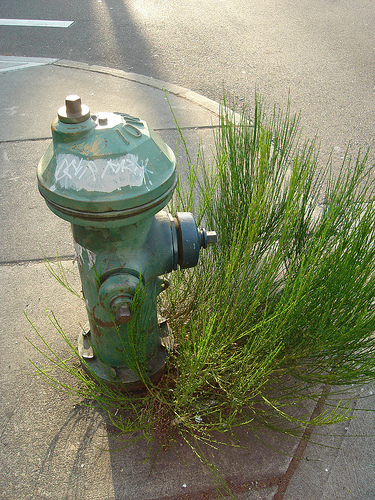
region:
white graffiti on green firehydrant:
[50, 154, 157, 199]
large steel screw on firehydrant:
[167, 206, 222, 279]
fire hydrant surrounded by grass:
[50, 294, 323, 452]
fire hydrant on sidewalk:
[12, 44, 198, 392]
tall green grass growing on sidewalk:
[191, 102, 353, 414]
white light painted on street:
[2, 11, 125, 42]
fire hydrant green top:
[35, 89, 181, 220]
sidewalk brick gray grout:
[247, 454, 309, 494]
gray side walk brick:
[4, 397, 59, 477]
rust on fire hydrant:
[87, 275, 137, 362]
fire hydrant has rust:
[0, 73, 215, 412]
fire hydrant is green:
[57, 95, 210, 436]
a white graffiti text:
[45, 143, 155, 208]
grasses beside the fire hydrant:
[154, 180, 302, 496]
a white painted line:
[29, 8, 137, 74]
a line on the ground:
[1, 10, 117, 60]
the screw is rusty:
[99, 296, 152, 346]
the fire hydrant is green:
[39, 114, 184, 390]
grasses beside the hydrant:
[96, 311, 311, 485]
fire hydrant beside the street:
[39, 39, 247, 396]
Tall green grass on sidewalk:
[147, 86, 368, 473]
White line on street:
[1, 6, 79, 37]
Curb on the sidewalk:
[37, 51, 347, 226]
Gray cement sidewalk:
[1, 50, 370, 496]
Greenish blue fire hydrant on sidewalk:
[26, 96, 215, 397]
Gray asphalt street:
[1, 0, 373, 210]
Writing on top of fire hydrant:
[105, 107, 151, 147]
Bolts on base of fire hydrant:
[68, 316, 184, 386]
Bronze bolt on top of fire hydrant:
[50, 92, 98, 128]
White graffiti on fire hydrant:
[44, 151, 149, 198]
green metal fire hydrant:
[42, 90, 205, 425]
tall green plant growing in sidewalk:
[171, 127, 374, 452]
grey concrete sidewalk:
[26, 48, 261, 137]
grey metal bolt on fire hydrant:
[55, 96, 88, 117]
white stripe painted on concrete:
[0, 11, 91, 40]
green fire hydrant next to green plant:
[47, 97, 283, 426]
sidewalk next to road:
[3, 0, 347, 141]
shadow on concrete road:
[66, 1, 174, 101]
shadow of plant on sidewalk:
[23, 405, 107, 480]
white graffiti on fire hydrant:
[51, 151, 152, 187]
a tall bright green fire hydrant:
[32, 92, 219, 390]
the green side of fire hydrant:
[97, 273, 147, 322]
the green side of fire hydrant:
[159, 208, 215, 274]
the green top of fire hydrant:
[39, 97, 170, 205]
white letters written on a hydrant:
[56, 152, 152, 183]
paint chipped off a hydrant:
[56, 150, 148, 190]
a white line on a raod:
[0, 15, 75, 30]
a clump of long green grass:
[24, 93, 371, 467]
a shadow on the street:
[2, 0, 178, 86]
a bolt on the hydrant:
[106, 365, 119, 377]